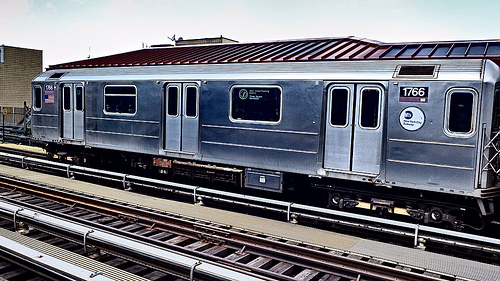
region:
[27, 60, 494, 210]
shiny train car with double doors between windows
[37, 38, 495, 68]
roof with vertical bars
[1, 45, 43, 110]
boxy brown building in front of train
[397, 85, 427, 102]
number in rectangle over purple line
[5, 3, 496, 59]
bright blue sky with faint clouds over train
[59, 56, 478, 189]
silver train on tracks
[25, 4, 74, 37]
white clouds in blue sky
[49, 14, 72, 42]
white clouds in blue sky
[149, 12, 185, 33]
white clouds in blue sky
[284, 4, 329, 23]
white clouds in blue sky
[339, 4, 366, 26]
white clouds in blue sky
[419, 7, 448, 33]
white clouds in blue sky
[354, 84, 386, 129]
this is a window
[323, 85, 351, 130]
this is a window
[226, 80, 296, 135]
this is a window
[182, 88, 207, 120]
this is a window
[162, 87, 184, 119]
this is a window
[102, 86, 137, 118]
this is a window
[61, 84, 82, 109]
this is a window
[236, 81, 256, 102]
number 7 train on the track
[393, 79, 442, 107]
train car number 1766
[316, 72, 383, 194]
Door on the train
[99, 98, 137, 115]
passengers in the window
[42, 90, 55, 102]
american flag on the train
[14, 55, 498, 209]
train car in the station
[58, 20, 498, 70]
roof of the station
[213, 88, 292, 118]
passengers in the train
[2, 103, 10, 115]
yellow sign in front of the train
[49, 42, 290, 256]
a train on a track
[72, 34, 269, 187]
a silver train on track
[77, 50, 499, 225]
a passenger train on track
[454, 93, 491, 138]
a train with window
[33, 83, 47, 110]
a train with window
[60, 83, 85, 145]
a train with door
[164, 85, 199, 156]
a train with door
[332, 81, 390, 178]
a train with door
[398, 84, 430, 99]
Train car number is 1766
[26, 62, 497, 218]
Train car has 3 double door entry ways on it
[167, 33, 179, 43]
Satellite dish is mounted on the roof of the station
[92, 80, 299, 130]
2 rectangular shaped windows in the center of the car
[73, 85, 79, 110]
dark glass window on the train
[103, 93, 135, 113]
dark glass window on the train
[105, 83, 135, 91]
dark glass window on the train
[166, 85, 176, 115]
dark glass window on the train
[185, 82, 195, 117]
dark glass window on the train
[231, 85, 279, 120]
dark glass window on the train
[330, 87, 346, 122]
dark glass window on the train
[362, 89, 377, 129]
dark glass window on the train